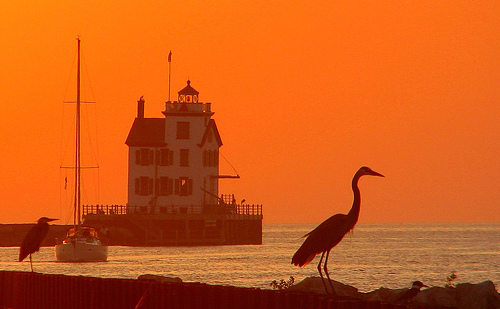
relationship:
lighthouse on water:
[123, 76, 223, 218] [9, 216, 498, 286]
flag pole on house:
[155, 46, 178, 101] [106, 86, 239, 238]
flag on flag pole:
[158, 45, 182, 61] [155, 46, 178, 101]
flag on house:
[158, 45, 182, 61] [106, 86, 239, 238]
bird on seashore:
[15, 214, 51, 271] [21, 246, 492, 306]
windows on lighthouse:
[127, 118, 219, 214] [79, 44, 261, 247]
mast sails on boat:
[72, 38, 84, 230] [52, 33, 109, 261]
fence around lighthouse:
[80, 202, 262, 222] [126, 49, 222, 218]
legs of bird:
[315, 246, 344, 301] [291, 155, 391, 303]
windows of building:
[135, 120, 194, 197] [118, 49, 230, 225]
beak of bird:
[366, 168, 385, 181] [290, 164, 383, 299]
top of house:
[128, 77, 221, 148] [123, 81, 227, 214]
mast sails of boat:
[72, 38, 84, 230] [56, 27, 110, 262]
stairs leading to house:
[122, 209, 171, 241] [68, 73, 265, 273]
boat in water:
[56, 27, 112, 260] [1, 222, 498, 292]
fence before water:
[0, 270, 407, 307] [1, 222, 498, 292]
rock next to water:
[294, 276, 359, 296] [366, 228, 498, 271]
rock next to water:
[294, 276, 500, 308] [366, 228, 498, 271]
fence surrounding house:
[83, 202, 262, 222] [117, 77, 235, 239]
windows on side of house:
[135, 120, 194, 197] [123, 81, 227, 214]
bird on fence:
[388, 278, 435, 306] [3, 279, 381, 307]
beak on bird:
[366, 168, 385, 181] [291, 155, 391, 303]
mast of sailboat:
[73, 36, 80, 236] [53, 224, 109, 261]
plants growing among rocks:
[267, 275, 297, 290] [138, 272, 499, 295]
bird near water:
[15, 214, 51, 271] [9, 216, 498, 286]